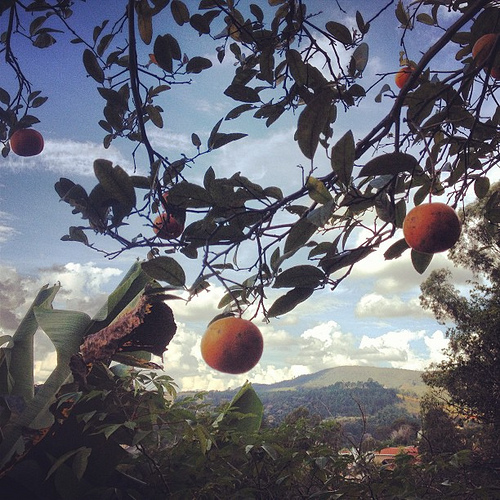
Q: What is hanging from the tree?
A: Orange.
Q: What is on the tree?
A: Leaves.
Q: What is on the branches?
A: Oranges.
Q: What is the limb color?
A: Brown.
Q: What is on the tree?
A: Oranges.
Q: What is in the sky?
A: Clouds.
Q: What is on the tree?
A: Orange.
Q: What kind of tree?
A: Orange.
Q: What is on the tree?
A: Leaves.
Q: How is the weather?
A: Sunny and clear.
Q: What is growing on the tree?
A: Peaches.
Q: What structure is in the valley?
A: A house.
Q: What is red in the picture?
A: Roof tops.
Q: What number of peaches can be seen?
A: 4.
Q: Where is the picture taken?
A: A tree.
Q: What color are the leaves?
A: Green.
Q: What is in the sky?
A: Clouds.